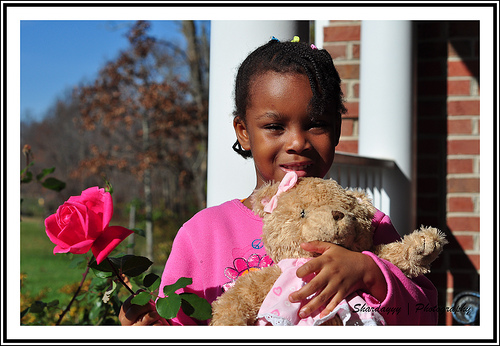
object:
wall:
[319, 19, 358, 149]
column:
[358, 20, 417, 237]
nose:
[284, 129, 314, 154]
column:
[207, 19, 310, 210]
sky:
[20, 20, 210, 129]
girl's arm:
[363, 213, 439, 325]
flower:
[44, 185, 134, 265]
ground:
[409, 149, 461, 176]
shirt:
[154, 197, 439, 325]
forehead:
[249, 69, 341, 112]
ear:
[233, 114, 251, 150]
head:
[233, 41, 342, 188]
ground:
[401, 119, 437, 147]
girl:
[118, 40, 438, 326]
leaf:
[156, 294, 183, 320]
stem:
[120, 275, 135, 294]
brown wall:
[418, 20, 480, 248]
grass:
[20, 217, 78, 303]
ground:
[16, 282, 70, 316]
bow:
[260, 171, 299, 215]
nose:
[330, 209, 343, 222]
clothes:
[253, 255, 387, 326]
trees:
[20, 20, 210, 279]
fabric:
[254, 256, 386, 326]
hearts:
[272, 285, 284, 297]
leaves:
[113, 254, 152, 277]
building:
[206, 20, 480, 325]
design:
[220, 251, 275, 291]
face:
[245, 69, 337, 183]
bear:
[208, 170, 450, 326]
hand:
[287, 239, 362, 318]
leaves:
[162, 275, 194, 296]